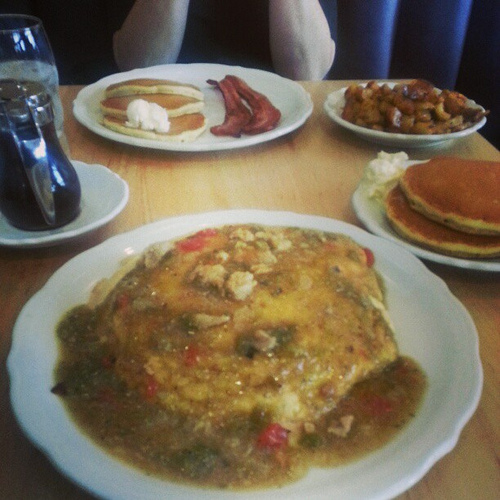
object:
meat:
[228, 64, 279, 137]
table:
[2, 76, 499, 498]